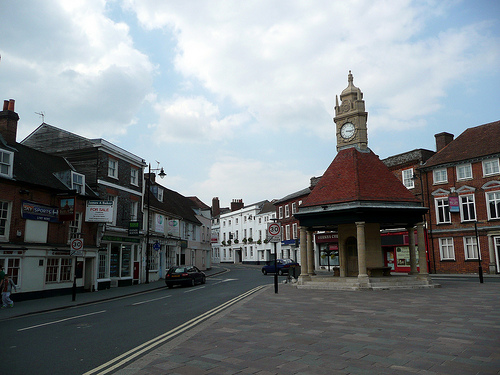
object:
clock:
[340, 122, 355, 138]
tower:
[333, 70, 368, 150]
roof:
[299, 147, 357, 208]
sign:
[266, 221, 281, 242]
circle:
[269, 223, 281, 235]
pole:
[274, 242, 279, 294]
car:
[165, 265, 206, 289]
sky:
[0, 0, 500, 209]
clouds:
[0, 0, 500, 210]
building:
[211, 196, 277, 264]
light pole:
[146, 162, 167, 284]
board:
[9, 218, 69, 243]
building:
[0, 99, 100, 303]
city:
[0, 69, 500, 375]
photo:
[0, 0, 500, 375]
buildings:
[0, 69, 500, 304]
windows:
[108, 156, 138, 185]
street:
[0, 264, 500, 375]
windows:
[229, 227, 262, 240]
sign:
[85, 200, 114, 223]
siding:
[364, 223, 384, 268]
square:
[109, 274, 500, 375]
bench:
[366, 267, 392, 278]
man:
[0, 274, 19, 308]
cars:
[165, 258, 299, 288]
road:
[0, 264, 295, 375]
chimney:
[0, 100, 19, 144]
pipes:
[3, 98, 16, 112]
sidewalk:
[0, 266, 228, 318]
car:
[262, 259, 300, 276]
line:
[15, 308, 107, 334]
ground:
[0, 260, 500, 375]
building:
[289, 69, 441, 292]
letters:
[271, 236, 281, 242]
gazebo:
[333, 69, 368, 152]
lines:
[15, 293, 171, 332]